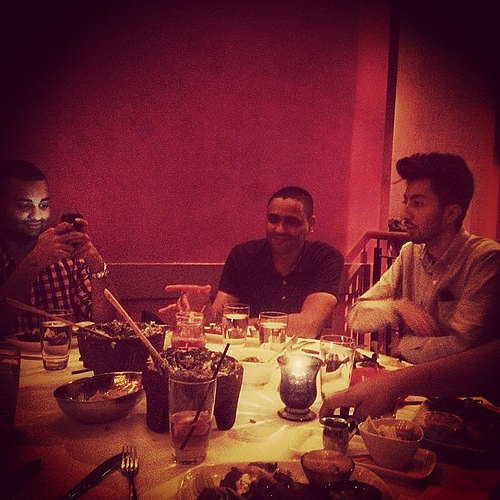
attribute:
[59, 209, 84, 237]
shirt — blue , white 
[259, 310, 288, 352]
glasses — water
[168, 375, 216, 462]
glass — empty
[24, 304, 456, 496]
table — dinner table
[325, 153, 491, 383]
man — seated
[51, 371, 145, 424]
bowl — gray , metal 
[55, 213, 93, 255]
phone — little , black 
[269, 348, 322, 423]
ambiance — lit candle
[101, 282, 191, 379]
spoon — wooden, serving spoon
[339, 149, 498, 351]
men — sitting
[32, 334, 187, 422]
bowl — stainless steel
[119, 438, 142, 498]
fork — silver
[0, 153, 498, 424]
friends — enjoying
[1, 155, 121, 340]
gentlement — young